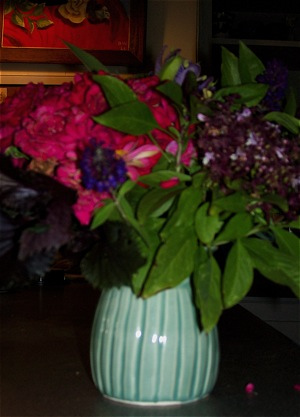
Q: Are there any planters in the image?
A: No, there are no planters.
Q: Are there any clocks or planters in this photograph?
A: No, there are no planters or clocks.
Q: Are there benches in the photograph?
A: No, there are no benches.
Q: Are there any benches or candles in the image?
A: No, there are no benches or candles.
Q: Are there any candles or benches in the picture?
A: No, there are no benches or candles.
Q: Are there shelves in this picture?
A: No, there are no shelves.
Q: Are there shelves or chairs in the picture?
A: No, there are no shelves or chairs.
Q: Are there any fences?
A: No, there are no fences.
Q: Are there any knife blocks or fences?
A: No, there are no fences or knife blocks.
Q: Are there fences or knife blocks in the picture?
A: No, there are no fences or knife blocks.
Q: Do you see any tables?
A: Yes, there is a table.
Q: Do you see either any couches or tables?
A: Yes, there is a table.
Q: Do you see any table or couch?
A: Yes, there is a table.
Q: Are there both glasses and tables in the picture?
A: No, there is a table but no glasses.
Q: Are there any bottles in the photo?
A: No, there are no bottles.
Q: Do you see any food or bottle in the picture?
A: No, there are no bottles or food.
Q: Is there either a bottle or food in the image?
A: No, there are no bottles or food.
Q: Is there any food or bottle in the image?
A: No, there are no bottles or food.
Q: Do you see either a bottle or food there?
A: No, there are no bottles or food.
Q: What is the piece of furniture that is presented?
A: The piece of furniture is a table.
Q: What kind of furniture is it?
A: The piece of furniture is a table.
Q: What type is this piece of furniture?
A: This is a table.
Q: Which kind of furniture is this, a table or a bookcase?
A: This is a table.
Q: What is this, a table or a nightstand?
A: This is a table.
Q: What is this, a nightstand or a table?
A: This is a table.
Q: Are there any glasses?
A: No, there are no glasses.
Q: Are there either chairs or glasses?
A: No, there are no glasses or chairs.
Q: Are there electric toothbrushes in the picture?
A: No, there are no electric toothbrushes.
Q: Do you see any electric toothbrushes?
A: No, there are no electric toothbrushes.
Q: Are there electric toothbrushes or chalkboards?
A: No, there are no electric toothbrushes or chalkboards.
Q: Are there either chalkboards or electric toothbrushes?
A: No, there are no electric toothbrushes or chalkboards.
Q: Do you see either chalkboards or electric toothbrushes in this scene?
A: No, there are no electric toothbrushes or chalkboards.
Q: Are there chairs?
A: No, there are no chairs.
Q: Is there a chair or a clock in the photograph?
A: No, there are no chairs or clocks.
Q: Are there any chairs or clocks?
A: No, there are no chairs or clocks.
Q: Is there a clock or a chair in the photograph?
A: No, there are no chairs or clocks.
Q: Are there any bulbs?
A: No, there are no bulbs.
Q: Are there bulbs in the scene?
A: No, there are no bulbs.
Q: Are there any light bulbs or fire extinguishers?
A: No, there are no light bulbs or fire extinguishers.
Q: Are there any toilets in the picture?
A: No, there are no toilets.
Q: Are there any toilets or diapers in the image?
A: No, there are no toilets or diapers.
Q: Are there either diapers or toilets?
A: No, there are no toilets or diapers.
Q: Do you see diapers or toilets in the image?
A: No, there are no toilets or diapers.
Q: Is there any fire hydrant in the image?
A: No, there are no fire hydrants.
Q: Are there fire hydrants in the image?
A: No, there are no fire hydrants.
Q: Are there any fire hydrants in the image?
A: No, there are no fire hydrants.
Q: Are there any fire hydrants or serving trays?
A: No, there are no fire hydrants or serving trays.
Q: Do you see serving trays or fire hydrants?
A: No, there are no fire hydrants or serving trays.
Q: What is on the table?
A: The flower is on the table.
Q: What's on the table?
A: The flower is on the table.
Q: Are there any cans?
A: No, there are no cans.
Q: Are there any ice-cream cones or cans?
A: No, there are no cans or ice-cream cones.